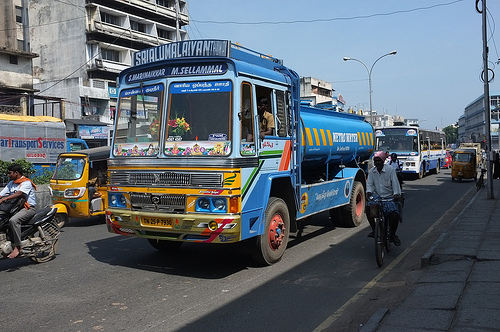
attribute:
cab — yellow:
[446, 148, 478, 180]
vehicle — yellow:
[42, 143, 114, 220]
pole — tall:
[480, 6, 494, 200]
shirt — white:
[309, 142, 425, 267]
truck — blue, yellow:
[102, 42, 392, 254]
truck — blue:
[401, 117, 440, 151]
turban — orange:
[375, 152, 385, 159]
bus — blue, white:
[373, 125, 450, 181]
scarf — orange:
[20, 175, 31, 188]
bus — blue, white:
[367, 125, 447, 182]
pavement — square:
[418, 226, 492, 321]